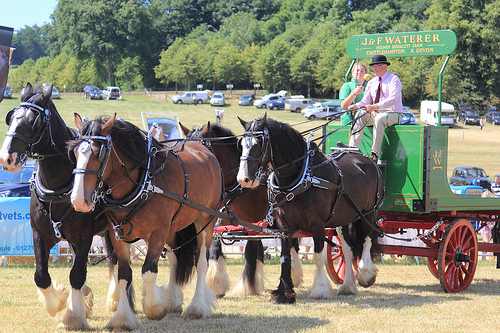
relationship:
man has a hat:
[337, 56, 401, 162] [368, 54, 390, 67]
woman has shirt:
[339, 62, 369, 126] [339, 78, 370, 125]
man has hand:
[337, 56, 401, 162] [366, 105, 379, 112]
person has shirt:
[339, 62, 369, 126] [339, 78, 370, 125]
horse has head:
[69, 112, 223, 325] [69, 113, 112, 212]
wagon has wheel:
[325, 32, 498, 294] [436, 218, 478, 293]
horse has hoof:
[237, 114, 383, 303] [275, 290, 296, 302]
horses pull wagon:
[0, 83, 384, 332] [325, 32, 498, 294]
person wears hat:
[337, 56, 401, 162] [368, 54, 390, 67]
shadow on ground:
[108, 315, 327, 333] [0, 270, 499, 332]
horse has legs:
[237, 114, 383, 303] [279, 207, 377, 300]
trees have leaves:
[27, 0, 497, 91] [196, 37, 338, 79]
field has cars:
[0, 87, 495, 166] [0, 84, 497, 127]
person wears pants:
[337, 56, 401, 162] [350, 109, 401, 167]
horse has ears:
[237, 114, 383, 303] [236, 113, 267, 130]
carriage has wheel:
[325, 32, 498, 294] [436, 218, 478, 293]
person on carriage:
[337, 56, 401, 162] [325, 32, 498, 294]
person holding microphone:
[339, 62, 369, 126] [361, 75, 369, 87]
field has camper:
[0, 87, 495, 166] [421, 100, 454, 128]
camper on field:
[421, 100, 454, 128] [0, 87, 495, 166]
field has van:
[0, 87, 495, 166] [287, 98, 313, 112]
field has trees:
[0, 87, 495, 166] [27, 0, 497, 91]